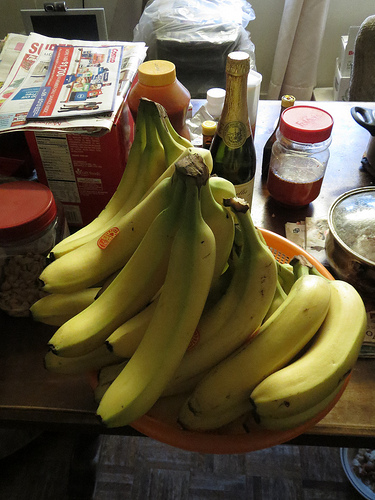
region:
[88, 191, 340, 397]
banana's sitting in a basket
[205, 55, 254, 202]
a wine bottle sitting behind banana's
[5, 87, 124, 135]
paper sitting on a box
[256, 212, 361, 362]
a basket of banana's on a table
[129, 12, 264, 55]
plastic attatched to furniture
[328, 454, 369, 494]
a plate sitting under a table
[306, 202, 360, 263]
a container sitting on the table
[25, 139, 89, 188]
a box sitting on a table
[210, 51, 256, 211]
a closed bottle of wine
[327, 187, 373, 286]
the pot is full of food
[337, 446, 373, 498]
a plate full of food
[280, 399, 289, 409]
a brown spot on the banana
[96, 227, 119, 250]
a red sticker on the banana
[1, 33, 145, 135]
a stack of newspapers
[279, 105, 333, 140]
the jar lid is red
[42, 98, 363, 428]
a pile of bananas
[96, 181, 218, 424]
the banana is yellow and green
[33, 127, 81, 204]
nutritional information on the box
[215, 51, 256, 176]
a bottle of champagne on the table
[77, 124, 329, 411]
bananas on the table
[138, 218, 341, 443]
an orange bowl under the bananas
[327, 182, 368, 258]
a pot on the table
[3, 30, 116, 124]
news papers on the table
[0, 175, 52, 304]
a plastic container on the table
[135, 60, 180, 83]
a yellow lid on a bottle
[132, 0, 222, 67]
a sack behind the table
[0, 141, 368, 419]
a wooden table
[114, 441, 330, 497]
floor under the table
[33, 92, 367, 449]
a bushel of bananas in a basket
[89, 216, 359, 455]
an orange basket overflowing with bananas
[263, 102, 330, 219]
jar with red liquid item inside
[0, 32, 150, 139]
small bundle of newspaper ads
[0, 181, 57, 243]
red cap on a glass jar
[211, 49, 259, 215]
bottle of unopened champagne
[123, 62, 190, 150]
squeeze bottle of hot sauce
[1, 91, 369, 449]
wooden table holding various items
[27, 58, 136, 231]
red box under the newspaper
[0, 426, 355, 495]
brown tile flooring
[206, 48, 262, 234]
a bottle of wine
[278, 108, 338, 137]
the lid is red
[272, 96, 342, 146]
the lid is red